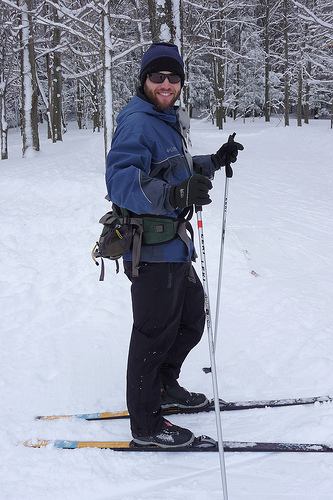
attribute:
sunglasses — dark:
[149, 73, 183, 83]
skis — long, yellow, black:
[199, 128, 235, 446]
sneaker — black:
[129, 418, 193, 454]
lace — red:
[165, 419, 175, 429]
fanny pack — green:
[140, 214, 179, 245]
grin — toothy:
[159, 91, 173, 99]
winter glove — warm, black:
[171, 174, 213, 210]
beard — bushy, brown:
[145, 86, 181, 109]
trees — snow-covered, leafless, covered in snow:
[2, 5, 331, 161]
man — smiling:
[92, 43, 244, 449]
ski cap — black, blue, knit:
[134, 43, 188, 87]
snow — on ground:
[7, 162, 125, 407]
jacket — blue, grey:
[105, 93, 216, 258]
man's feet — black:
[128, 383, 210, 447]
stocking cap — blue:
[140, 41, 184, 69]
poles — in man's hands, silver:
[176, 157, 231, 499]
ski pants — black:
[127, 263, 205, 439]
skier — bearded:
[26, 41, 332, 454]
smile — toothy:
[158, 92, 172, 97]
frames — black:
[151, 71, 179, 78]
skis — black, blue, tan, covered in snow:
[24, 395, 332, 451]